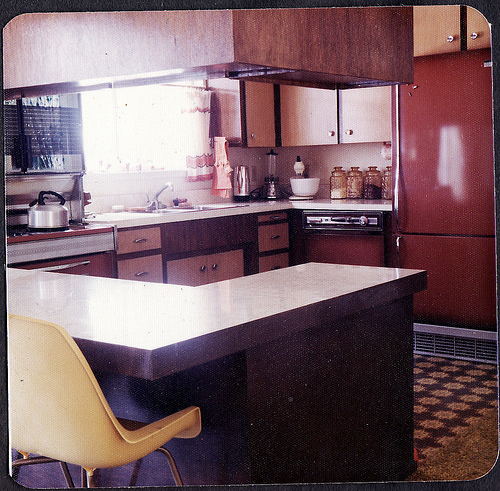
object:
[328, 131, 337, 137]
knob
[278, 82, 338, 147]
cabinet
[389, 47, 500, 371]
refrigerator freezer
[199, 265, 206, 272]
knob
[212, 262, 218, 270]
knob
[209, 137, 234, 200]
dish towel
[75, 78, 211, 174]
window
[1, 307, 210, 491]
chair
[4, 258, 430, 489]
counter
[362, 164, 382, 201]
container counter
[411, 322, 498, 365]
vent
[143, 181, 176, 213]
faucet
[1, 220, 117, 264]
stove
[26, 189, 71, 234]
kettle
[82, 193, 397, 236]
countertop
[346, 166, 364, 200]
food jar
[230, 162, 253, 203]
coffee pot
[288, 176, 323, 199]
bowl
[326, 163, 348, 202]
jar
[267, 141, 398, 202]
wall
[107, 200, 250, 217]
sink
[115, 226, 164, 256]
drawer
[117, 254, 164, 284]
drawer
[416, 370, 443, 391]
tile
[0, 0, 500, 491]
kitchen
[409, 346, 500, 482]
floor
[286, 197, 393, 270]
counter